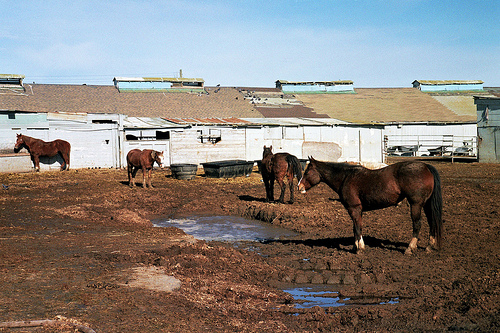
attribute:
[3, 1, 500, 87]
sky — blue, clear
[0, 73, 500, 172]
barn — open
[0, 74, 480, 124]
roof — grey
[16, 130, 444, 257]
horses — muddy, standing, four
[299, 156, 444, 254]
horse — standing, brown, white, small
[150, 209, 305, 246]
water — pool, dirty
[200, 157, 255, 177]
tubs — square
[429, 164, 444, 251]
tail — black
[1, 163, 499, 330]
ground — muddy, land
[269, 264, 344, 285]
mud — puddles, land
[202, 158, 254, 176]
container — black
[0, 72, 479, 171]
building — white, blue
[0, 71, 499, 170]
structures — wooden